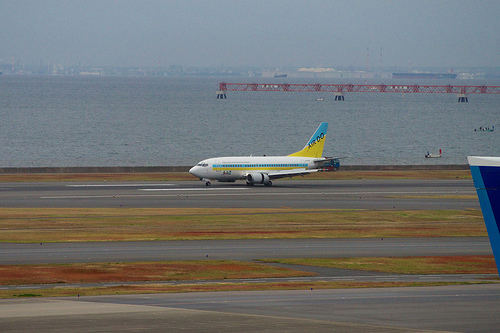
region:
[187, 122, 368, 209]
The airplane is yellow, blue, and white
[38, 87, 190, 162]
The ocean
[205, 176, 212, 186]
Front tire on airplane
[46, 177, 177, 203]
The roadway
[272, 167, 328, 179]
Wing on the airplane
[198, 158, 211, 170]
Windshield of the airplane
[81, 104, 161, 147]
The ocean water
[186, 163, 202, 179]
Nose of the airplane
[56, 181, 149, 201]
Roadway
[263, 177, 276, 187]
Back wheel of airplane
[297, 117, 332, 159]
The tail of the plane.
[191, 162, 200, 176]
The nose of the plane.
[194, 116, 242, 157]
The windows of the cockpit area.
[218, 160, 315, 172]
The passenger windows on the side of the plane.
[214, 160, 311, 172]
The blue and yellow stripes on the side of the plane.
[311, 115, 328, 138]
The blue paint on the tail.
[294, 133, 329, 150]
The yellow paint on the tail.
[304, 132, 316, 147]
The word Air on the tail of the plane.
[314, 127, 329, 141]
The word Do on the tail of the plane.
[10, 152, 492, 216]
The runway the plane is driving on.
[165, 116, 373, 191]
white airplane with yellow and blue stripes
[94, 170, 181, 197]
airport runway with white lines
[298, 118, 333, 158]
yellow and blue tail fin on airplane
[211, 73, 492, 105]
red structure over the water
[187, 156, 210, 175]
cockpit window on the plane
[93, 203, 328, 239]
strip of grass by airplane runway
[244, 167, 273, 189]
propeller on an airplane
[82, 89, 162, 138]
ripples and waves in the water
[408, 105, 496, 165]
things floating in the water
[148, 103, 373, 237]
plane about to take off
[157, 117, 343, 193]
Airplane on the runway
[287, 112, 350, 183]
Airplane with yellow and blue tail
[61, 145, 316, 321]
three airplane runways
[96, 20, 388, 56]
Foggy grey sky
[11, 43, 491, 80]
City in the skyline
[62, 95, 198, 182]
Runway beside a body of water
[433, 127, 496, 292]
Tail of an airplane on the first runway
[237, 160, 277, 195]
Dual engine airplane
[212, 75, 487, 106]
Structures in the water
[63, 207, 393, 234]
Brown grass on the runway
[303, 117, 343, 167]
light blue and yellow tail wing of plane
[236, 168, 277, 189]
engine on left side of plane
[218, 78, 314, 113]
red metal structure in water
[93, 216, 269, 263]
red , yellow and grey runway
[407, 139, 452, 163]
red floating bouy in water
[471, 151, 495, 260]
blue and white structure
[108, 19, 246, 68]
hazy sky in distance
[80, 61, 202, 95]
buildings in the distance behind water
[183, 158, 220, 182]
nose of plane with windshield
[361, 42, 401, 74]
two tall red and white pillars